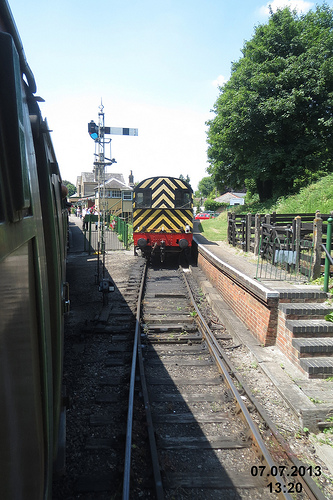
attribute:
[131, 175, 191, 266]
train — black and yellow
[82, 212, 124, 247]
fence — green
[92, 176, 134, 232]
building — yellow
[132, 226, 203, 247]
train — red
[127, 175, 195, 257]
train — black, yellow, large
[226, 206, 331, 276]
fence — little, brown, wooden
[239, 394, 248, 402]
stone — small, white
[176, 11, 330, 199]
bush — big, green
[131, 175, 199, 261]
train — black, yellow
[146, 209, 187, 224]
stripes — black, yellow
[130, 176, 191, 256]
train — black , yellow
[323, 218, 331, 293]
post — long, green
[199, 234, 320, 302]
platform — small, bricked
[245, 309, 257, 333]
brick — red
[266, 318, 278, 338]
brick — red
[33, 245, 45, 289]
paint — yellow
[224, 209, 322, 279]
fence — little, wooden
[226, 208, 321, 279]
gate — wooden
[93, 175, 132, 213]
house — yellow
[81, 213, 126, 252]
fence — green, metal